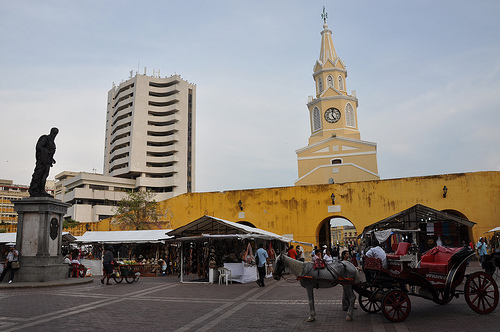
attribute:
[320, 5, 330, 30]
steeple — large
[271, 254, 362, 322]
horse — white, brown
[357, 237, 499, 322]
carriage — red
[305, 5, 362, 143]
tower — tall, yellow, tan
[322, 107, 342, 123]
clock — white, black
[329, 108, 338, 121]
hands — black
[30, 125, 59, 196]
statue — tall, of a man, black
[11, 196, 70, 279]
base — stone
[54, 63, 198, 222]
building — tall, white, multi floored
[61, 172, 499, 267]
wall — yellow, long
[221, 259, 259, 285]
chair — white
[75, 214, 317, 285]
tent — long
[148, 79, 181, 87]
window — curved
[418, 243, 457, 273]
seat — red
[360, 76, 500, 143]
clouds — white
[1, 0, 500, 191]
sky — blue